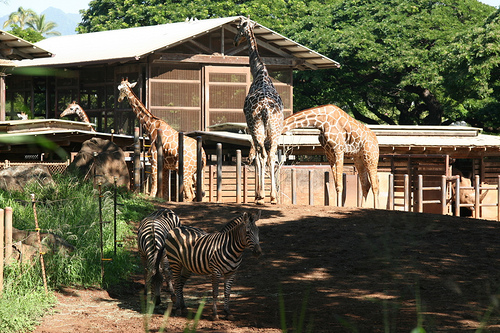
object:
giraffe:
[245, 102, 384, 212]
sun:
[0, 0, 81, 31]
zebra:
[139, 208, 266, 319]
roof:
[20, 16, 343, 76]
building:
[0, 15, 341, 210]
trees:
[332, 5, 479, 104]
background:
[0, 0, 484, 132]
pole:
[176, 131, 186, 202]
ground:
[281, 219, 497, 333]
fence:
[0, 174, 118, 289]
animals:
[136, 206, 264, 324]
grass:
[17, 196, 108, 261]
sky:
[22, 0, 82, 31]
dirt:
[330, 227, 414, 286]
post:
[215, 142, 223, 203]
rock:
[61, 135, 136, 197]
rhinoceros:
[442, 174, 489, 218]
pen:
[387, 171, 499, 219]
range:
[0, 1, 82, 23]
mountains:
[37, 1, 77, 36]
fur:
[182, 232, 230, 264]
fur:
[328, 126, 367, 150]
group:
[357, 0, 500, 121]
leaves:
[449, 105, 471, 121]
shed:
[188, 119, 500, 220]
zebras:
[134, 208, 184, 307]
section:
[47, 175, 126, 269]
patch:
[290, 262, 406, 301]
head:
[243, 134, 264, 167]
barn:
[191, 121, 500, 222]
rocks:
[0, 160, 60, 203]